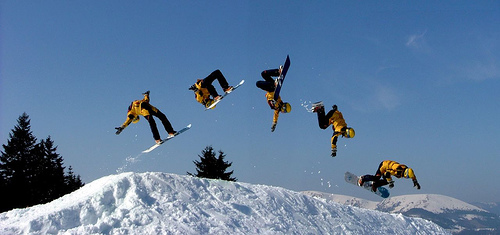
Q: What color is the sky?
A: Blue.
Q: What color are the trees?
A: Green.